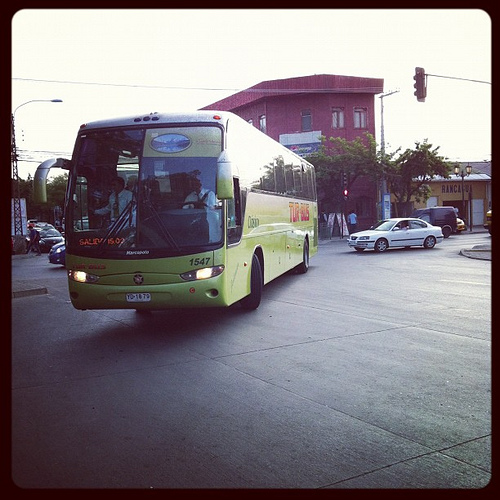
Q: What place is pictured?
A: It is a road.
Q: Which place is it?
A: It is a road.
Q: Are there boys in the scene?
A: No, there are no boys.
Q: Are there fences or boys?
A: No, there are no boys or fences.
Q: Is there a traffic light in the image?
A: Yes, there is a traffic light.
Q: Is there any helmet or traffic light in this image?
A: Yes, there is a traffic light.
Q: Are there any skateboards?
A: No, there are no skateboards.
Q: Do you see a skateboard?
A: No, there are no skateboards.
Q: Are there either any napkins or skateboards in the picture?
A: No, there are no skateboards or napkins.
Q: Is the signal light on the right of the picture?
A: Yes, the signal light is on the right of the image.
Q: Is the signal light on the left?
A: No, the signal light is on the right of the image.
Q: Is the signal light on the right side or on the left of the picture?
A: The signal light is on the right of the image.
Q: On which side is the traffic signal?
A: The traffic signal is on the right of the image.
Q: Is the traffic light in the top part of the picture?
A: Yes, the traffic light is in the top of the image.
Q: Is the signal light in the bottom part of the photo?
A: No, the signal light is in the top of the image.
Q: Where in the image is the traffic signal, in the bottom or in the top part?
A: The traffic signal is in the top of the image.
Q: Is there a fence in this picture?
A: No, there are no fences.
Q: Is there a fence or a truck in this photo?
A: No, there are no fences or trucks.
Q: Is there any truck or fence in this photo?
A: No, there are no fences or trucks.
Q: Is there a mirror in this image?
A: Yes, there is a mirror.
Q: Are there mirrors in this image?
A: Yes, there is a mirror.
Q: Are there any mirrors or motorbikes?
A: Yes, there is a mirror.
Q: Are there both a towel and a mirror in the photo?
A: No, there is a mirror but no towels.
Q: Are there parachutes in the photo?
A: No, there are no parachutes.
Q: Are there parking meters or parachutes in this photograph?
A: No, there are no parachutes or parking meters.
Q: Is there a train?
A: No, there are no trains.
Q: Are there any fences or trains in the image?
A: No, there are no trains or fences.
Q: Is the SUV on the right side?
A: Yes, the SUV is on the right of the image.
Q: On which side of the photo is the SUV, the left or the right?
A: The SUV is on the right of the image.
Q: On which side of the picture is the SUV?
A: The SUV is on the right of the image.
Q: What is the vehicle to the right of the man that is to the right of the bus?
A: The vehicle is a SUV.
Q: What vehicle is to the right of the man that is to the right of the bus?
A: The vehicle is a SUV.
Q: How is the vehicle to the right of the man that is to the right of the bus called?
A: The vehicle is a SUV.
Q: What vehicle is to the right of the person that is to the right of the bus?
A: The vehicle is a SUV.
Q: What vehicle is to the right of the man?
A: The vehicle is a SUV.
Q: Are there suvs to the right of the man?
A: Yes, there is a SUV to the right of the man.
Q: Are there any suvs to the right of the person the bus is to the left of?
A: Yes, there is a SUV to the right of the man.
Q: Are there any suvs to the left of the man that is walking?
A: No, the SUV is to the right of the man.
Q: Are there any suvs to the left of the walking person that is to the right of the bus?
A: No, the SUV is to the right of the man.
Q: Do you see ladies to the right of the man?
A: No, there is a SUV to the right of the man.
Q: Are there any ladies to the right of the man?
A: No, there is a SUV to the right of the man.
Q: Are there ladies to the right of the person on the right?
A: No, there is a SUV to the right of the man.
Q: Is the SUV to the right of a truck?
A: No, the SUV is to the right of the man.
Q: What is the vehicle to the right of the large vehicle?
A: The vehicle is a SUV.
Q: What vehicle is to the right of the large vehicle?
A: The vehicle is a SUV.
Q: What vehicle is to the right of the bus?
A: The vehicle is a SUV.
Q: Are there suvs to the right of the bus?
A: Yes, there is a SUV to the right of the bus.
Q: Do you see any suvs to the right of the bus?
A: Yes, there is a SUV to the right of the bus.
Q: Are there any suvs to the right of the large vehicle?
A: Yes, there is a SUV to the right of the bus.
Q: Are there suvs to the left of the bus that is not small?
A: No, the SUV is to the right of the bus.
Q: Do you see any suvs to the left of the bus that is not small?
A: No, the SUV is to the right of the bus.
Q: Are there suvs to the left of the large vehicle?
A: No, the SUV is to the right of the bus.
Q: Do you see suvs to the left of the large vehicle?
A: No, the SUV is to the right of the bus.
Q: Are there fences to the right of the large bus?
A: No, there is a SUV to the right of the bus.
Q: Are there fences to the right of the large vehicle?
A: No, there is a SUV to the right of the bus.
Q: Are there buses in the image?
A: Yes, there is a bus.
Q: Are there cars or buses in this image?
A: Yes, there is a bus.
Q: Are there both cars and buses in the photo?
A: Yes, there are both a bus and a car.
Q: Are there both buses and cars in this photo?
A: Yes, there are both a bus and a car.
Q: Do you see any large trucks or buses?
A: Yes, there is a large bus.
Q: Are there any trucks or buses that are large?
A: Yes, the bus is large.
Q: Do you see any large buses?
A: Yes, there is a large bus.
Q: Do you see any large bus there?
A: Yes, there is a large bus.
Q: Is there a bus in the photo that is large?
A: Yes, there is a bus that is large.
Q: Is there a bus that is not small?
A: Yes, there is a large bus.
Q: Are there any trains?
A: No, there are no trains.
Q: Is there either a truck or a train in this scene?
A: No, there are no trains or trucks.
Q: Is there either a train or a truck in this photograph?
A: No, there are no trains or trucks.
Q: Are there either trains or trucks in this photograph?
A: No, there are no trains or trucks.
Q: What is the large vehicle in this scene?
A: The vehicle is a bus.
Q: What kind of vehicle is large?
A: The vehicle is a bus.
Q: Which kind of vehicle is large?
A: The vehicle is a bus.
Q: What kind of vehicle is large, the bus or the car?
A: The bus is large.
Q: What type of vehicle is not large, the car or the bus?
A: The car is not large.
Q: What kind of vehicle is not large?
A: The vehicle is a car.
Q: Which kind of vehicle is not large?
A: The vehicle is a car.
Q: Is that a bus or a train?
A: That is a bus.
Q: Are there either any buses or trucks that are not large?
A: No, there is a bus but it is large.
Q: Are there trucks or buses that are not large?
A: No, there is a bus but it is large.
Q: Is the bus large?
A: Yes, the bus is large.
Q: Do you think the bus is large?
A: Yes, the bus is large.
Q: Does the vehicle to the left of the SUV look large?
A: Yes, the bus is large.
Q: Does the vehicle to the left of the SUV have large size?
A: Yes, the bus is large.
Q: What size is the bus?
A: The bus is large.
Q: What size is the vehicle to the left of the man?
A: The bus is large.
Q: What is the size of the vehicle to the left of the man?
A: The bus is large.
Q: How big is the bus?
A: The bus is large.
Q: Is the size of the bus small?
A: No, the bus is large.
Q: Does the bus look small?
A: No, the bus is large.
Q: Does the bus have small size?
A: No, the bus is large.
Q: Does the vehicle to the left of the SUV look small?
A: No, the bus is large.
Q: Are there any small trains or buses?
A: No, there is a bus but it is large.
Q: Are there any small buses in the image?
A: No, there is a bus but it is large.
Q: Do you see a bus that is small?
A: No, there is a bus but it is large.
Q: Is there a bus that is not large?
A: No, there is a bus but it is large.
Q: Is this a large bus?
A: Yes, this is a large bus.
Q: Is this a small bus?
A: No, this is a large bus.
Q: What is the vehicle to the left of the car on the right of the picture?
A: The vehicle is a bus.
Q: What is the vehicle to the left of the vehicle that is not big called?
A: The vehicle is a bus.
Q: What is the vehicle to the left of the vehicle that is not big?
A: The vehicle is a bus.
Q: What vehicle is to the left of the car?
A: The vehicle is a bus.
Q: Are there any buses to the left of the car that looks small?
A: Yes, there is a bus to the left of the car.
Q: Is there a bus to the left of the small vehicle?
A: Yes, there is a bus to the left of the car.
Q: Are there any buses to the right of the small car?
A: No, the bus is to the left of the car.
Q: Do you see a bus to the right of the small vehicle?
A: No, the bus is to the left of the car.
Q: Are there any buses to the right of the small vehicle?
A: No, the bus is to the left of the car.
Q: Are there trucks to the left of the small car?
A: No, there is a bus to the left of the car.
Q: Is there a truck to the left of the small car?
A: No, there is a bus to the left of the car.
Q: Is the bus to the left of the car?
A: Yes, the bus is to the left of the car.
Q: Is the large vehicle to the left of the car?
A: Yes, the bus is to the left of the car.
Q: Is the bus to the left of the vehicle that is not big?
A: Yes, the bus is to the left of the car.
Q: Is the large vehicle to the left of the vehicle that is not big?
A: Yes, the bus is to the left of the car.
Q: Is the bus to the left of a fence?
A: No, the bus is to the left of the car.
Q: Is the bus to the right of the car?
A: No, the bus is to the left of the car.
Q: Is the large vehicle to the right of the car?
A: No, the bus is to the left of the car.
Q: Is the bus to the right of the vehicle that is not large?
A: No, the bus is to the left of the car.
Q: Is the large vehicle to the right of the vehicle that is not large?
A: No, the bus is to the left of the car.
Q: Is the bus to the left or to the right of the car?
A: The bus is to the left of the car.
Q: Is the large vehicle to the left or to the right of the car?
A: The bus is to the left of the car.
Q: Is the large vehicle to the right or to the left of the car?
A: The bus is to the left of the car.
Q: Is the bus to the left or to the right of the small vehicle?
A: The bus is to the left of the car.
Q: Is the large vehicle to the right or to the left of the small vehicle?
A: The bus is to the left of the car.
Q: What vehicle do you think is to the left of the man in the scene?
A: The vehicle is a bus.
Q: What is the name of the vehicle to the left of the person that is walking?
A: The vehicle is a bus.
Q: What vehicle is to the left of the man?
A: The vehicle is a bus.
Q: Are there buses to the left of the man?
A: Yes, there is a bus to the left of the man.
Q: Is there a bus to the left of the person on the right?
A: Yes, there is a bus to the left of the man.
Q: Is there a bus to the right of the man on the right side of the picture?
A: No, the bus is to the left of the man.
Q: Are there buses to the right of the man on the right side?
A: No, the bus is to the left of the man.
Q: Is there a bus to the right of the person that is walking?
A: No, the bus is to the left of the man.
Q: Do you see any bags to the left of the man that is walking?
A: No, there is a bus to the left of the man.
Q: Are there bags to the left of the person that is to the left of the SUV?
A: No, there is a bus to the left of the man.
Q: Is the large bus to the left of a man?
A: Yes, the bus is to the left of a man.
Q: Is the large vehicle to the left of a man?
A: Yes, the bus is to the left of a man.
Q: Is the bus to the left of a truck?
A: No, the bus is to the left of a man.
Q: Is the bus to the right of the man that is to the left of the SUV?
A: No, the bus is to the left of the man.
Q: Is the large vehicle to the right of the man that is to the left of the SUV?
A: No, the bus is to the left of the man.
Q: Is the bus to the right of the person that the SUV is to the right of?
A: No, the bus is to the left of the man.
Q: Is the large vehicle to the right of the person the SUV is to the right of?
A: No, the bus is to the left of the man.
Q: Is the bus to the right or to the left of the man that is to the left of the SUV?
A: The bus is to the left of the man.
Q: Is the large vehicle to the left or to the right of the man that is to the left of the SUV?
A: The bus is to the left of the man.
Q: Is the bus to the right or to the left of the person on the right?
A: The bus is to the left of the man.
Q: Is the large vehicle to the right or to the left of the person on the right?
A: The bus is to the left of the man.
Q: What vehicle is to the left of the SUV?
A: The vehicle is a bus.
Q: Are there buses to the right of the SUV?
A: No, the bus is to the left of the SUV.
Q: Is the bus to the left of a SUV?
A: Yes, the bus is to the left of a SUV.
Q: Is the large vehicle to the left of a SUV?
A: Yes, the bus is to the left of a SUV.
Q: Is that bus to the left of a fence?
A: No, the bus is to the left of a SUV.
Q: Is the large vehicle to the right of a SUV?
A: No, the bus is to the left of a SUV.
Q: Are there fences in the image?
A: No, there are no fences.